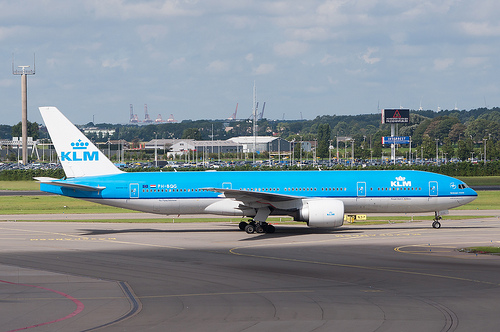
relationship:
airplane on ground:
[33, 105, 479, 234] [1, 169, 498, 329]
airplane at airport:
[33, 105, 479, 234] [5, 135, 483, 327]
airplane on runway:
[33, 105, 479, 234] [6, 205, 483, 327]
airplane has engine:
[33, 105, 479, 234] [297, 192, 347, 234]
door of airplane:
[355, 180, 366, 200] [33, 105, 479, 234]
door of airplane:
[424, 177, 438, 199] [33, 105, 479, 234]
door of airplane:
[127, 182, 142, 199] [33, 105, 479, 234]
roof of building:
[227, 132, 289, 147] [225, 130, 301, 162]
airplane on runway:
[23, 102, 490, 241] [6, 180, 482, 327]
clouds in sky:
[455, 18, 494, 40] [5, 1, 480, 128]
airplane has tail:
[23, 102, 490, 241] [31, 93, 133, 218]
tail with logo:
[31, 93, 133, 218] [52, 132, 104, 161]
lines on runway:
[28, 226, 119, 253] [48, 227, 484, 311]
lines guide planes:
[28, 226, 119, 253] [10, 99, 470, 240]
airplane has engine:
[33, 105, 479, 234] [290, 194, 351, 230]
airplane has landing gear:
[33, 105, 479, 234] [430, 217, 442, 228]